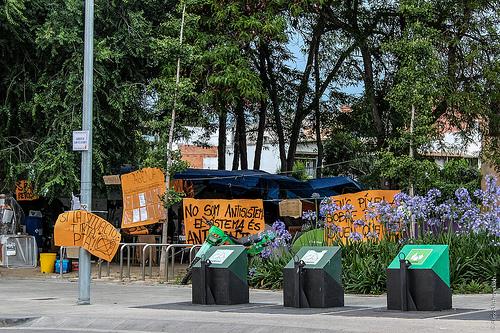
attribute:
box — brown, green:
[373, 227, 454, 308]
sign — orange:
[323, 189, 400, 245]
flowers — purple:
[357, 151, 499, 225]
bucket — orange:
[36, 250, 60, 273]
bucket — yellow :
[178, 222, 269, 328]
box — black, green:
[186, 241, 256, 308]